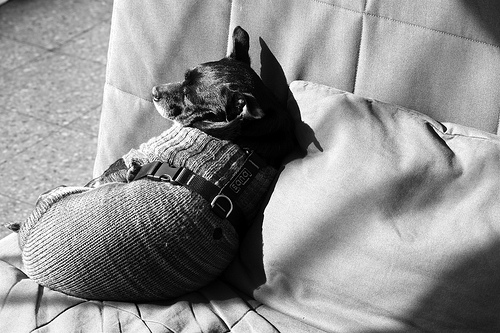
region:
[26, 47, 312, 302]
the dog is sitting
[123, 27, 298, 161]
the dog has ears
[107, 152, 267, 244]
the dog is wearing strap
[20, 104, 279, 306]
dog is wearing sweater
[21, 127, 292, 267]
the sweater is knitted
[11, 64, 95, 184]
the floor is tiled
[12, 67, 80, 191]
the floor is made of marble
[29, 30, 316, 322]
dog on the couch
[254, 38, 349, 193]
the shadow on the couch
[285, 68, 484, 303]
pillow on the couch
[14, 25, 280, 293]
a dog in a chair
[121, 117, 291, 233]
a harness on a dog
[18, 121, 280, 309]
a sweater on a dog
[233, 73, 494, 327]
a pillow under a dog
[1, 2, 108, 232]
a tile floor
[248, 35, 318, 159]
a shadow of a dog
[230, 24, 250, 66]
an ear on a dog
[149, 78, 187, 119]
a dark muzzle on a dog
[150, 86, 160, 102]
a little black nose on a dog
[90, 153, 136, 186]
a front paw on a dog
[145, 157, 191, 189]
Plastic harness clasp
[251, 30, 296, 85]
Shadow of dogs ear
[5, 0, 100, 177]
Square tiles on ground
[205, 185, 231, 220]
Metal D-Ring on harness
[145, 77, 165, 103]
Little black nose of dog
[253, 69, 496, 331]
Pillow dog is reclining against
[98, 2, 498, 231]
Quilted back of chair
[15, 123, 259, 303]
Sweater of little dog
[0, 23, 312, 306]
Dog reclining on chair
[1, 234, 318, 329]
Blanket under dog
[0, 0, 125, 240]
Tiled floor next to the dog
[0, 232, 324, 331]
Cover on the bed the dog is laying on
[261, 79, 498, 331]
Pillow on the bed the dog is leaning on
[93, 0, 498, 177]
Back upright part of the bed the dog lays on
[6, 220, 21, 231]
Tip of the dog's tail peeking out of its sweater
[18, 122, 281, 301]
Ribbed knit sweater the dog is wearing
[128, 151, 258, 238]
Strap around the dog's sweater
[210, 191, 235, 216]
U-shaped buckle on the dog's sweater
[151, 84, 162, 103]
Small black nose on the dog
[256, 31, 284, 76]
Dog's black pointy left ear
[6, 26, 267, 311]
The dog in the sweater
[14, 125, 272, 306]
The sweater the dog is wearing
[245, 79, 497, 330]
The pillow behind the dog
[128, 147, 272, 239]
The harness on the dog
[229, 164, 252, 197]
The writing on the harness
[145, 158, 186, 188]
The harness buckle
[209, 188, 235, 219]
The metal loop on the harness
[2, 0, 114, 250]
The tiles on the ground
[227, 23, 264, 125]
The dog's ears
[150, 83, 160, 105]
The nose of the dog